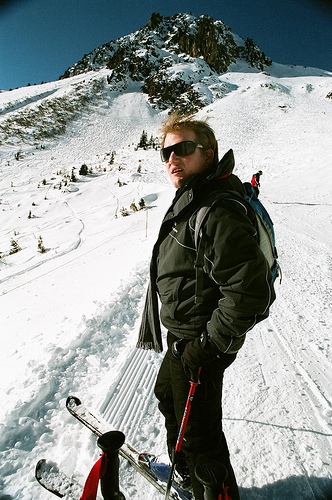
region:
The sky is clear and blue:
[11, 1, 76, 65]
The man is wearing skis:
[33, 393, 176, 498]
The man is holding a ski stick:
[156, 350, 204, 497]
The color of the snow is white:
[28, 270, 140, 366]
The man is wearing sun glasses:
[152, 135, 204, 165]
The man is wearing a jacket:
[134, 150, 278, 362]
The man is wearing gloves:
[174, 325, 216, 384]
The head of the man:
[157, 112, 220, 193]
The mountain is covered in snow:
[67, 13, 268, 114]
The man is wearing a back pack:
[189, 178, 287, 318]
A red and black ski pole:
[152, 346, 216, 498]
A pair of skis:
[21, 377, 199, 496]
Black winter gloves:
[181, 325, 229, 385]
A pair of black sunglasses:
[155, 134, 212, 167]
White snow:
[3, 25, 330, 496]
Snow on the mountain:
[12, 11, 329, 241]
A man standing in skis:
[29, 115, 296, 498]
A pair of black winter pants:
[145, 337, 245, 493]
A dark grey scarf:
[140, 182, 167, 357]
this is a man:
[112, 98, 273, 496]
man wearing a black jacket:
[129, 129, 257, 387]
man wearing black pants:
[136, 279, 254, 498]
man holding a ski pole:
[146, 302, 217, 478]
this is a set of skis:
[17, 361, 177, 498]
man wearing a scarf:
[133, 181, 204, 356]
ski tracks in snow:
[54, 280, 167, 478]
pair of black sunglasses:
[156, 134, 201, 169]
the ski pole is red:
[168, 335, 245, 495]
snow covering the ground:
[45, 259, 128, 386]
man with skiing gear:
[137, 108, 286, 496]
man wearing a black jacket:
[143, 170, 262, 361]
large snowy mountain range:
[81, 4, 300, 146]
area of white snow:
[86, 194, 125, 245]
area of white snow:
[60, 264, 117, 310]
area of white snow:
[18, 308, 67, 357]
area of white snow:
[258, 424, 313, 469]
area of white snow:
[244, 358, 279, 408]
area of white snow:
[295, 234, 318, 275]